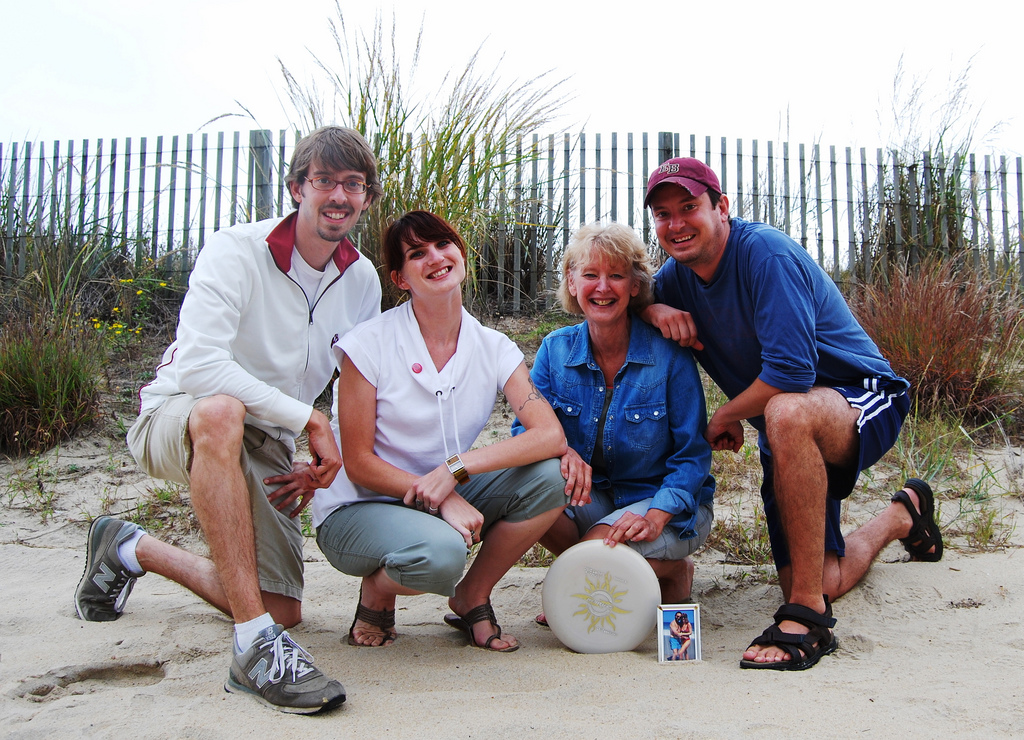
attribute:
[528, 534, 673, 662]
frisbee — round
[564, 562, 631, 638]
design — sun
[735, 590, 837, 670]
sandal — dark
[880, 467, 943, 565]
sandal — dark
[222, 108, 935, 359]
fence — brown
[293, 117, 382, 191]
hair — dark brown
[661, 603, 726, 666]
cap — burgundy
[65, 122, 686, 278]
fence — long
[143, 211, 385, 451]
jacket — white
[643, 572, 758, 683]
picture — small blue and white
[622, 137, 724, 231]
hat — red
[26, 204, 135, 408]
flowers — yellow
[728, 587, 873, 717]
sandals — black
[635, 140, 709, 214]
hat — burgundy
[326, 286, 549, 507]
sweater — white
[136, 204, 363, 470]
sweater — red and white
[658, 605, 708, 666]
photo — small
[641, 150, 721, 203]
hat — red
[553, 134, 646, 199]
fence — thin